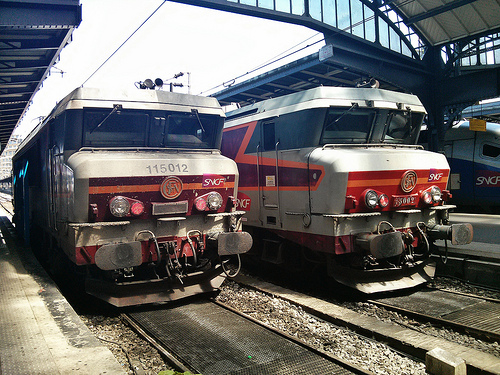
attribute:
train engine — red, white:
[7, 76, 254, 306]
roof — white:
[223, 85, 433, 128]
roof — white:
[8, 85, 227, 152]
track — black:
[90, 295, 362, 372]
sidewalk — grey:
[1, 207, 131, 373]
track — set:
[366, 299, 498, 341]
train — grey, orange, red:
[56, 77, 231, 345]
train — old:
[17, 76, 257, 318]